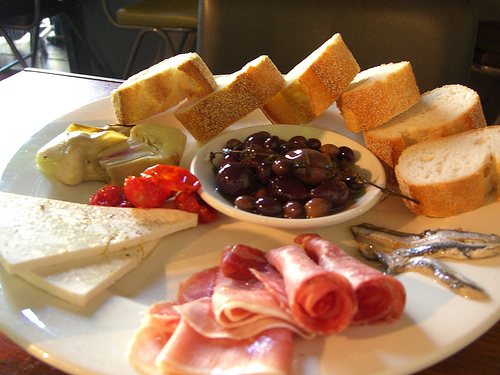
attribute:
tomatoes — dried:
[82, 159, 221, 235]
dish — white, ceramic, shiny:
[190, 124, 385, 227]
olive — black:
[319, 144, 340, 156]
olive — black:
[292, 137, 307, 145]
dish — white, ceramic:
[1, 75, 499, 373]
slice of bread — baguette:
[174, 56, 287, 146]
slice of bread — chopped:
[260, 33, 361, 125]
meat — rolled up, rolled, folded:
[133, 234, 406, 374]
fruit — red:
[90, 164, 222, 225]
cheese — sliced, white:
[0, 189, 199, 273]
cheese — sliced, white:
[15, 234, 164, 306]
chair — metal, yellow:
[104, 0, 199, 80]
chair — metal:
[0, 1, 108, 77]